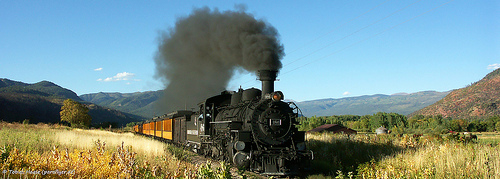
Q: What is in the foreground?
A: Train.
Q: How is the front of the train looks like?
A: Black in color.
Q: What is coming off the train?
A: Smoke.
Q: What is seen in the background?
A: Low mountains.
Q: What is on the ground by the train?
A: A shadow.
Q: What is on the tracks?
A: A train.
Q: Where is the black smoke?
A: Coming out of the train.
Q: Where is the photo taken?
A: Outside in the country.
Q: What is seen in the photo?
A: A train.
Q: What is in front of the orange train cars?
A: A black locomotive.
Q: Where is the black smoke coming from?
A: A train.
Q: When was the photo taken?
A: Daytime.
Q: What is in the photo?
A: A steam train.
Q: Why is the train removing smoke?
A: To enable its movement.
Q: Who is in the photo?
A: No one.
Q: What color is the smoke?
A: Black.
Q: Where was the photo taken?
A: On the train tracks.